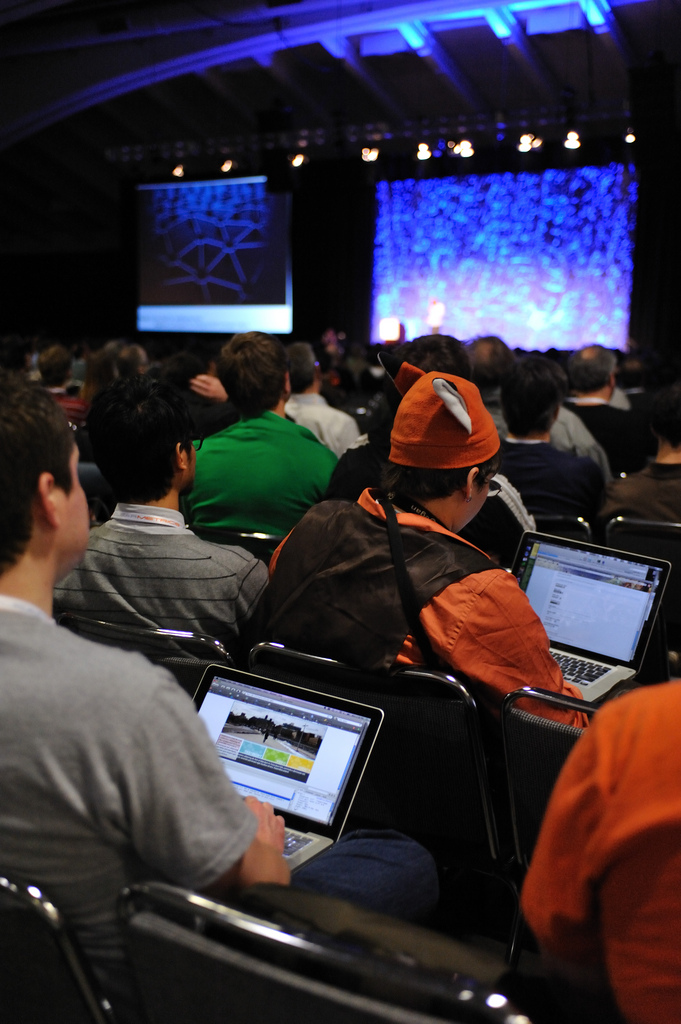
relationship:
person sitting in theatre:
[516, 681, 674, 1016] [6, 14, 658, 1021]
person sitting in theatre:
[491, 356, 599, 535] [6, 14, 658, 1021]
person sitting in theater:
[185, 330, 332, 541] [6, 6, 673, 1017]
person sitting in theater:
[34, 340, 70, 399] [6, 6, 673, 1017]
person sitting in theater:
[281, 338, 350, 459] [6, 6, 673, 1017]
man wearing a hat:
[260, 363, 580, 731] [358, 354, 514, 487]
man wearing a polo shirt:
[186, 327, 344, 530] [207, 419, 328, 544]